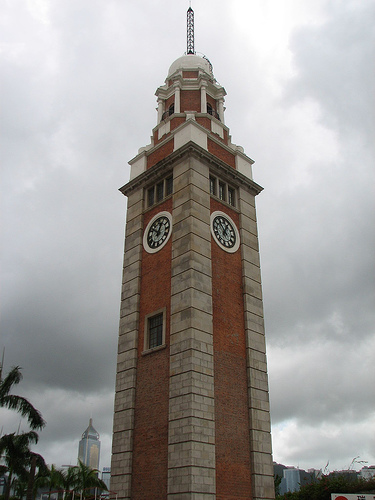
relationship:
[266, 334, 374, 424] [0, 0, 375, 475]
cloud in cloudy sky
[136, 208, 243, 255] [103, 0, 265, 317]
clock on tower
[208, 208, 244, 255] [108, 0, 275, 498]
clock on buildings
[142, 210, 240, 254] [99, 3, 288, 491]
clock on tower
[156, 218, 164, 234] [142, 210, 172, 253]
black hands on clock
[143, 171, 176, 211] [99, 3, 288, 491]
window on tower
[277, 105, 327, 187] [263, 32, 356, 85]
white clouds in blue sky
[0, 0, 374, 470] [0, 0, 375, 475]
cloud in cloudy sky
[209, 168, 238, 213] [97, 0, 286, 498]
window on building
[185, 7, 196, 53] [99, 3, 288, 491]
lightning rod on tower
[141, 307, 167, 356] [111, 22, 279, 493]
window on tower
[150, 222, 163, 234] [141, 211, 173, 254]
black hands on clock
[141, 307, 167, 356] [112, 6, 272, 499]
window on building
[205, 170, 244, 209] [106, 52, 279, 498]
window in building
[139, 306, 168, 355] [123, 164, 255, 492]
window in building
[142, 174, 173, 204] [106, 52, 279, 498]
window in building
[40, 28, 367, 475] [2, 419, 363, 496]
buildings in background